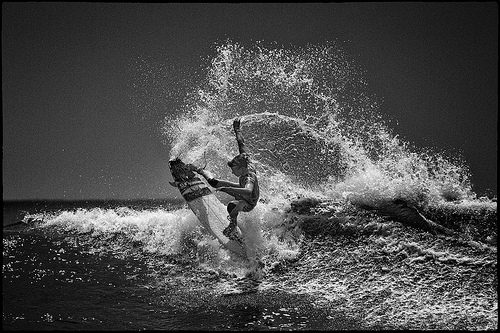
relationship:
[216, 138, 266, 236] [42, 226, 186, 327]
man in water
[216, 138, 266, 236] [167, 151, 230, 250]
man on board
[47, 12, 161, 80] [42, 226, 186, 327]
sky above water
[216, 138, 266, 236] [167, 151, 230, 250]
man in board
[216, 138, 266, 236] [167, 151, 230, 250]
man riding board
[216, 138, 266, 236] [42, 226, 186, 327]
man on water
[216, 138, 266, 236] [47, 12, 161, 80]
man near sky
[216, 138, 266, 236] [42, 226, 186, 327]
man near water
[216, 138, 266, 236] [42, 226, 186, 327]
man by water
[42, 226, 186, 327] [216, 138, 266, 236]
water on man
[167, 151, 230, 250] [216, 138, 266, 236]
board near man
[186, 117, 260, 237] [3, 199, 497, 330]
surfer in ocean